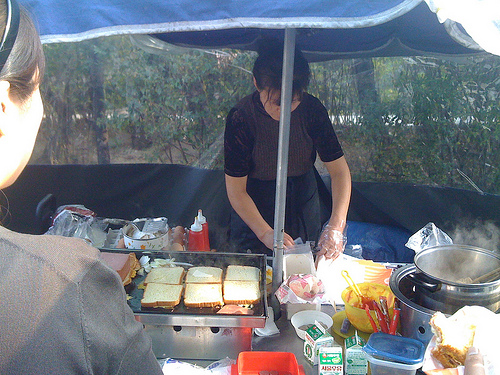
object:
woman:
[224, 37, 353, 260]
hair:
[251, 42, 313, 107]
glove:
[314, 214, 349, 262]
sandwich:
[140, 281, 184, 309]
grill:
[98, 247, 268, 362]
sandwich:
[143, 266, 186, 285]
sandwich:
[184, 282, 223, 308]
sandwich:
[223, 281, 261, 303]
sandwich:
[184, 266, 222, 283]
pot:
[388, 243, 498, 346]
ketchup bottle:
[187, 215, 205, 253]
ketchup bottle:
[194, 208, 211, 254]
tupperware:
[362, 331, 425, 374]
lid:
[363, 332, 426, 363]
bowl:
[342, 283, 395, 333]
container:
[228, 351, 306, 374]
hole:
[418, 325, 426, 335]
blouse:
[223, 92, 347, 182]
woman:
[0, 0, 165, 374]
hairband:
[0, 0, 21, 69]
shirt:
[0, 225, 138, 375]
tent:
[16, 0, 500, 61]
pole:
[269, 27, 298, 320]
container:
[315, 345, 344, 375]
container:
[344, 330, 368, 375]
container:
[304, 321, 335, 366]